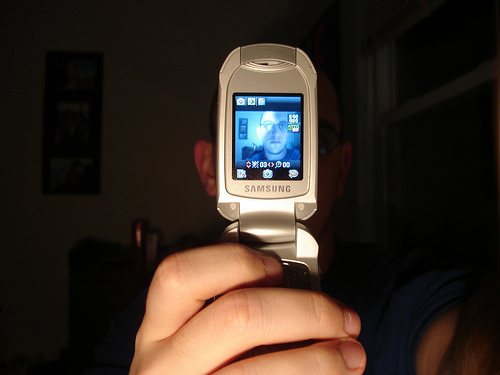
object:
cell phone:
[215, 43, 319, 293]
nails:
[343, 306, 360, 336]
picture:
[234, 95, 300, 169]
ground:
[417, 174, 484, 231]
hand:
[130, 244, 365, 375]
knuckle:
[133, 244, 366, 375]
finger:
[143, 244, 366, 375]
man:
[128, 78, 496, 375]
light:
[136, 230, 141, 247]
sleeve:
[355, 275, 458, 374]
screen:
[232, 92, 302, 179]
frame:
[380, 41, 461, 158]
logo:
[245, 186, 290, 193]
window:
[357, 0, 500, 245]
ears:
[194, 140, 216, 196]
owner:
[247, 111, 304, 163]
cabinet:
[0, 0, 376, 358]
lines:
[234, 290, 264, 324]